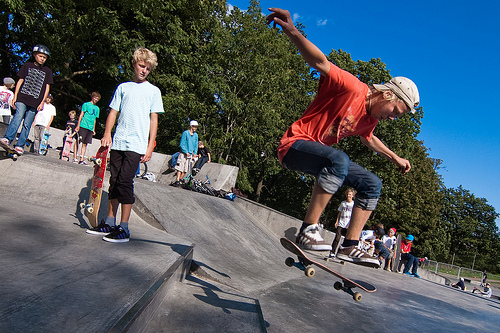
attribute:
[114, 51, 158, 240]
boy — young 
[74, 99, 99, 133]
shirt — Green 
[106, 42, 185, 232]
boy — Young 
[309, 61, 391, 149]
shirt — orange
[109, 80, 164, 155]
tee shirt — White 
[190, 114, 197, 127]
helmet — white 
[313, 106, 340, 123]
shirt — black 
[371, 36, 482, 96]
sky — blue , clear 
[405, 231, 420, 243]
cap — blue 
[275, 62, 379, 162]
tee shirt — red 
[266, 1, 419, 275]
boy — doing trick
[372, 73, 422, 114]
cap — Beige 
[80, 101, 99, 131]
shirt — green 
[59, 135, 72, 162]
skateboard — red 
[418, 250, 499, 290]
barricades — metal 